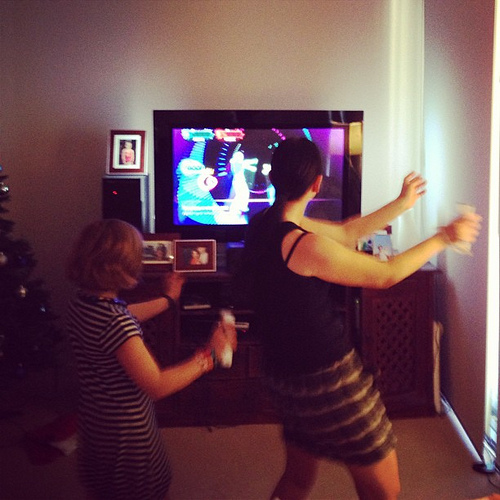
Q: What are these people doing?
A: Dancing.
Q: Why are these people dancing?
A: It's a game.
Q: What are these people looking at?
A: A TV.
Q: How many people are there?
A: Two.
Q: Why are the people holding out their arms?
A: They are dancing.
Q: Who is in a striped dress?
A: The girl on the left.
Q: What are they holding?
A: Controllers.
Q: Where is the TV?
A: On a stand.